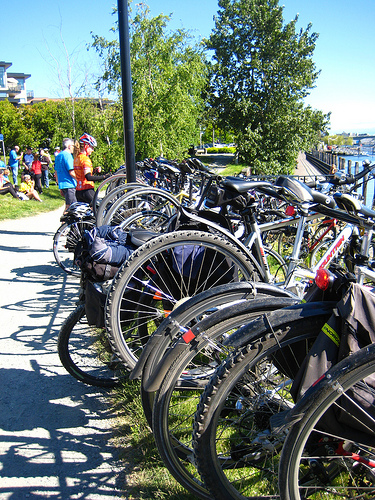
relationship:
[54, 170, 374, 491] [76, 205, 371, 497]
bikes on grass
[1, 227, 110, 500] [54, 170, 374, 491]
shadow of bikes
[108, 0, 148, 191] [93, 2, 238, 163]
pole in middle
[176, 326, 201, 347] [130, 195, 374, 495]
reflector on bike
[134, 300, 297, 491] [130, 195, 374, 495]
tire of bike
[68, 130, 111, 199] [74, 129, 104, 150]
person wears helmet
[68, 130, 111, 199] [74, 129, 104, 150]
rider with helmet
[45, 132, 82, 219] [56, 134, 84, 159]
man with gray hair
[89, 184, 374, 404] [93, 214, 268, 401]
bicycle has rear tire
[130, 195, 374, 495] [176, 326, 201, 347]
bike has reflector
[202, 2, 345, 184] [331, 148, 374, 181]
tree next water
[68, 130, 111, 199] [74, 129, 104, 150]
person with helmet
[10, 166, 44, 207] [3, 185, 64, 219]
woman sits on grass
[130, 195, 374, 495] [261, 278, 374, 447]
bike has bikebag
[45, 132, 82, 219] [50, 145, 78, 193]
man has blue shirts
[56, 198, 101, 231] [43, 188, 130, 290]
helmet on bike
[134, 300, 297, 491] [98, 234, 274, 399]
tire in front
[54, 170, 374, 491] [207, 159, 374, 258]
bike in a rack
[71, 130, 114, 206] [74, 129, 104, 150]
person with helmet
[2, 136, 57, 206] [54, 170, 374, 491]
people near bikes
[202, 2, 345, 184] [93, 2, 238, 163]
tree withouth leaves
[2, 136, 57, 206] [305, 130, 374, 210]
people near beach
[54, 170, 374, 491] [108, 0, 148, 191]
bikes near pole